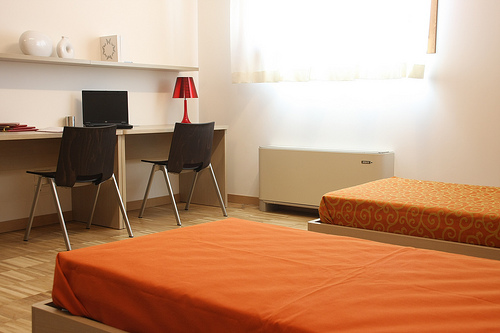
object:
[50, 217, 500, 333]
fabric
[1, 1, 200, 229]
wall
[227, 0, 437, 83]
curtain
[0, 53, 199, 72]
shelf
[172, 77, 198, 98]
lampshade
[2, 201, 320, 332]
floor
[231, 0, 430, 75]
window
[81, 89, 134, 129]
laptop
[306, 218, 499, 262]
box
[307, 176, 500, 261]
bed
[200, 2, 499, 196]
wall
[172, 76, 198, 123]
lamp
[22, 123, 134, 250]
chair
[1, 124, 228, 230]
desk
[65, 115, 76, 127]
cup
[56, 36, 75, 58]
sculpture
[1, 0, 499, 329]
room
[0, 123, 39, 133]
folder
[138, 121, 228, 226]
chair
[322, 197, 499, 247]
pattern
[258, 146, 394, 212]
radiator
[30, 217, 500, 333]
bed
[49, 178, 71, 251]
leg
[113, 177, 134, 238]
leg